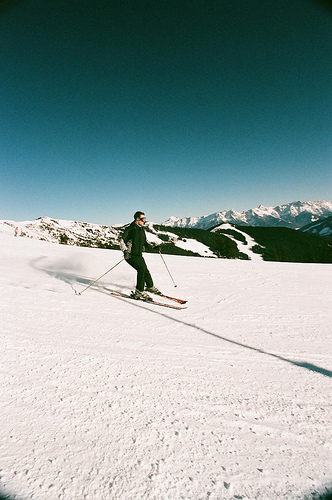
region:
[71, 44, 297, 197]
The sky is blue.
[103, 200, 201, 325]
The man is skiing downhill.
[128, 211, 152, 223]
The man is wearing goggles.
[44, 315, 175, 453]
The ground is snow covered.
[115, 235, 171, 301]
the man has black pants on.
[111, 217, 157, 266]
The man is wearing a black jacket.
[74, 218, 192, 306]
He is wearing grey boots.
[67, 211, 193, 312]
The man has poles.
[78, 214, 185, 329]
He is on skies.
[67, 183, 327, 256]
The mountains are snow covered.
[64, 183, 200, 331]
A man skiing on snow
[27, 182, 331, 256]
Snow covered mountains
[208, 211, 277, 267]
A ski slope in the distance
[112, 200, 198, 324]
A man on down hill skiis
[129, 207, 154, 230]
A man wearing goggles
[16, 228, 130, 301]
The shadow of a man skiing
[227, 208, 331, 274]
Trees on the hill side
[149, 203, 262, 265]
Trees in the distance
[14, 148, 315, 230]
Blue sky above the mountains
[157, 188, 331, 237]
Mountains beyond the trees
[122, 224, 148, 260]
black and white winter jacket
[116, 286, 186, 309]
red skis in snow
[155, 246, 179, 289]
yellow metal ski pole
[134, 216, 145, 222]
ski goggles on face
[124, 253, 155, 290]
black padded snow pants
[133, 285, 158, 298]
grey and white boots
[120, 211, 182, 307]
man skiing on hill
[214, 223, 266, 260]
snow on hill top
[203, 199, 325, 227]
snow covered mountain peak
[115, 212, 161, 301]
man wearing ski clothes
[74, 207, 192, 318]
man skiing down hill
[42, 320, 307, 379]
ski tracks in snow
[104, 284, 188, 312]
red and white skis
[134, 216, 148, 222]
goggles on man's face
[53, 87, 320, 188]
clear cloudless blue sky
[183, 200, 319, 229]
snowy mountain tops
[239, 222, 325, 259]
grey rocky mountain tops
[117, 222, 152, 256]
black and white ski jacket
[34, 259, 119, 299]
shadow of skier on snow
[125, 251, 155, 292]
black ski pants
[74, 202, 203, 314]
man skiing down a slop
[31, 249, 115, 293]
snow blowing from the man's skis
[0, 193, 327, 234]
snow capped mountains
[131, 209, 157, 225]
man wearing goggles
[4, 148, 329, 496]
powdery snow covered ground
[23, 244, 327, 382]
sun casting shadows on snow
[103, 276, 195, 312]
man using red skis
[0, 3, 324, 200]
sky with many shades of blue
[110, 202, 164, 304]
man wearing black ski gear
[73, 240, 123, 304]
ski pole digging into snow